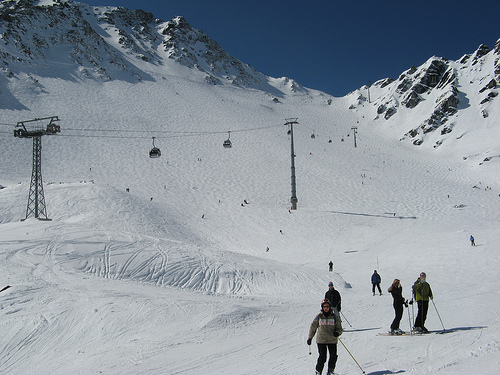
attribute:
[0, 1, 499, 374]
snow — white, coled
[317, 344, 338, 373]
pants — black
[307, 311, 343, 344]
jacket — gray, black, brown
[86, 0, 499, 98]
sky — clear, blue, cloudless, dark blue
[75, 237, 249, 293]
ski tracks — from skiers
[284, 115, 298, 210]
pole — metal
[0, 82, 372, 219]
ski lift — for carrying skiers, running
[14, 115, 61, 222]
tower — metal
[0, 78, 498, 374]
ski slope — snowy, mountainous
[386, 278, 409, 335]
skier — female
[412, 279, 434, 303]
jacket — tan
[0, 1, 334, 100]
mountain — rocky, snowy, steep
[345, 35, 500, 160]
mountain — rocky, steep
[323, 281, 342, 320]
skier — skiing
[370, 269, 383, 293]
skier — alone, without ski poles, skiing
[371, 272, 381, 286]
jacket — blue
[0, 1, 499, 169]
mountains — snow covered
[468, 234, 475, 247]
skier — skiing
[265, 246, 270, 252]
skier — skiing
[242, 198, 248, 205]
skier — skiing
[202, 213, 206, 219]
skier — skiing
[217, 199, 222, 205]
skier — skiing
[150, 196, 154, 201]
skier — skiing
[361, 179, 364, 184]
skier — skiing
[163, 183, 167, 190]
skier — skiing